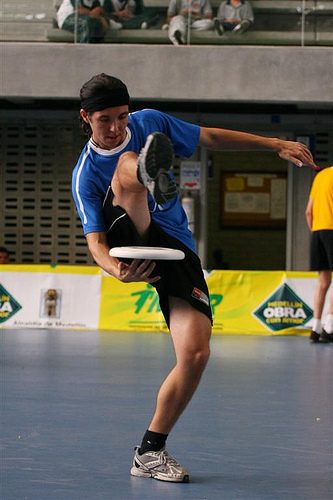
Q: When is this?
A: Daytime.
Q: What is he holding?
A: Frisbee.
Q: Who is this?
A: Man.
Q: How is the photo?
A: Clear.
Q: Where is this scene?
A: On a court.